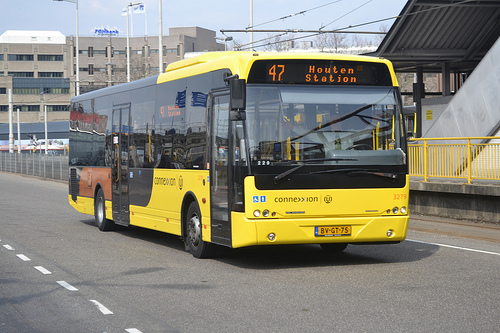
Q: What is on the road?
A: Bus.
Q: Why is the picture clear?
A: The sunlight.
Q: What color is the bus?
A: Yellow.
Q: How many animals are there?
A: Zero.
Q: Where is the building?
A: In the background.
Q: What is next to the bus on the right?
A: The bus stop.